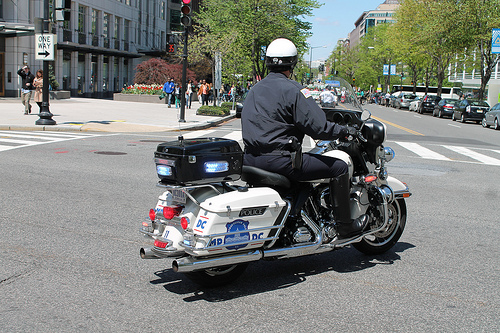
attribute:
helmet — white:
[258, 34, 300, 67]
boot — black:
[337, 211, 369, 238]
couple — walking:
[19, 63, 43, 115]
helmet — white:
[240, 19, 330, 74]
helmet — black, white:
[263, 36, 298, 71]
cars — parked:
[389, 90, 414, 110]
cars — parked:
[405, 94, 423, 114]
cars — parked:
[415, 92, 442, 113]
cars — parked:
[432, 95, 460, 118]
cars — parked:
[452, 95, 489, 124]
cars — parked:
[477, 97, 499, 130]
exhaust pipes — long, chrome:
[135, 247, 338, 272]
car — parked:
[397, 90, 498, 139]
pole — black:
[35, 4, 56, 129]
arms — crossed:
[33, 79, 42, 89]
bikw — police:
[140, 74, 410, 284]